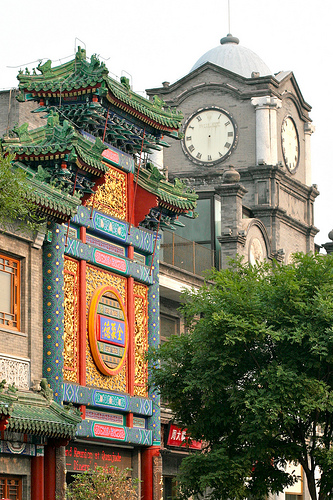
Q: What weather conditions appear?
A: It is cloudy.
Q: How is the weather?
A: It is cloudy.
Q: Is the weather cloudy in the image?
A: Yes, it is cloudy.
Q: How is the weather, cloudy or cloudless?
A: It is cloudy.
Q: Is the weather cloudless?
A: No, it is cloudy.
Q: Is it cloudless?
A: No, it is cloudy.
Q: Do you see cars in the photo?
A: No, there are no cars.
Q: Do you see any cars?
A: No, there are no cars.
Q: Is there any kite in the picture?
A: No, there are no kites.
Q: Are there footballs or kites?
A: No, there are no kites or footballs.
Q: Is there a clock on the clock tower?
A: Yes, there are clocks on the clock tower.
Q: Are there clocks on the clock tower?
A: Yes, there are clocks on the clock tower.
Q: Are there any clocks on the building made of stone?
A: Yes, there are clocks on the clock tower.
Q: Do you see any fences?
A: Yes, there is a fence.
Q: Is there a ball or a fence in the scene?
A: Yes, there is a fence.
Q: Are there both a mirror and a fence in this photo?
A: No, there is a fence but no mirrors.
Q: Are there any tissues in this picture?
A: No, there are no tissues.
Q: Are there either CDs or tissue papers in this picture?
A: No, there are no tissue papers or cds.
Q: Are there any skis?
A: No, there are no skis.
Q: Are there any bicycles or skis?
A: No, there are no skis or bicycles.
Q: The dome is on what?
A: The dome is on the clock tower.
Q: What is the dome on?
A: The dome is on the clock tower.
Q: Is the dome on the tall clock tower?
A: Yes, the dome is on the clock tower.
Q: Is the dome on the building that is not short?
A: Yes, the dome is on the clock tower.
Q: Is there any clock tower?
A: Yes, there is a clock tower.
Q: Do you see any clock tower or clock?
A: Yes, there is a clock tower.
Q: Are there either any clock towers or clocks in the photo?
A: Yes, there is a clock tower.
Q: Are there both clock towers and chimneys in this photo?
A: No, there is a clock tower but no chimneys.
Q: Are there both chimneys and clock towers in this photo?
A: No, there is a clock tower but no chimneys.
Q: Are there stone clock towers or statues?
A: Yes, there is a stone clock tower.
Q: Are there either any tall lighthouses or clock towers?
A: Yes, there is a tall clock tower.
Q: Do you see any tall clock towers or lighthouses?
A: Yes, there is a tall clock tower.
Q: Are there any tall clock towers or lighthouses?
A: Yes, there is a tall clock tower.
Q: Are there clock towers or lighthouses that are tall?
A: Yes, the clock tower is tall.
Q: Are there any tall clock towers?
A: Yes, there is a tall clock tower.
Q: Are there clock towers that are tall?
A: Yes, there is a clock tower that is tall.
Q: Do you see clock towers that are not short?
A: Yes, there is a tall clock tower.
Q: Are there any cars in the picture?
A: No, there are no cars.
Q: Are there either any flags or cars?
A: No, there are no cars or flags.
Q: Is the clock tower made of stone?
A: Yes, the clock tower is made of stone.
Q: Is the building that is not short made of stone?
A: Yes, the clock tower is made of stone.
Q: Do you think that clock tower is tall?
A: Yes, the clock tower is tall.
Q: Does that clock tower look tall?
A: Yes, the clock tower is tall.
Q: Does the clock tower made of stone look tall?
A: Yes, the clock tower is tall.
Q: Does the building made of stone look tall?
A: Yes, the clock tower is tall.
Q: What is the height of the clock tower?
A: The clock tower is tall.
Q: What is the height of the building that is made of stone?
A: The clock tower is tall.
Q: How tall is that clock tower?
A: The clock tower is tall.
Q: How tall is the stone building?
A: The clock tower is tall.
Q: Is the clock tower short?
A: No, the clock tower is tall.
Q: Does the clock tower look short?
A: No, the clock tower is tall.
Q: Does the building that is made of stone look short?
A: No, the clock tower is tall.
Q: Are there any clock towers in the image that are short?
A: No, there is a clock tower but it is tall.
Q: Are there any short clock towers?
A: No, there is a clock tower but it is tall.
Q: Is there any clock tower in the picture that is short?
A: No, there is a clock tower but it is tall.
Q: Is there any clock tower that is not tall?
A: No, there is a clock tower but it is tall.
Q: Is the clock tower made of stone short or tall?
A: The clock tower is tall.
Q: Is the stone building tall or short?
A: The clock tower is tall.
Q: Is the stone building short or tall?
A: The clock tower is tall.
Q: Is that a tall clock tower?
A: Yes, that is a tall clock tower.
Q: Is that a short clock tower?
A: No, that is a tall clock tower.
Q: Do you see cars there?
A: No, there are no cars.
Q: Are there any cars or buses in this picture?
A: No, there are no cars or buses.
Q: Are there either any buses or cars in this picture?
A: No, there are no cars or buses.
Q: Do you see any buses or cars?
A: No, there are no cars or buses.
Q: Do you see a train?
A: No, there are no trains.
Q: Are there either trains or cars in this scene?
A: No, there are no trains or cars.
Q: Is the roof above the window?
A: Yes, the roof is above the window.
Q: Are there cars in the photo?
A: No, there are no cars.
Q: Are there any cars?
A: No, there are no cars.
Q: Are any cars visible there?
A: No, there are no cars.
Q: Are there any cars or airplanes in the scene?
A: No, there are no cars or airplanes.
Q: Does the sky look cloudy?
A: Yes, the sky is cloudy.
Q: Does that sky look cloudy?
A: Yes, the sky is cloudy.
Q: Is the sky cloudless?
A: No, the sky is cloudy.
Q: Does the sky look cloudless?
A: No, the sky is cloudy.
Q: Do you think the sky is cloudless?
A: No, the sky is cloudy.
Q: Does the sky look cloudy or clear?
A: The sky is cloudy.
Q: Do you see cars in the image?
A: No, there are no cars.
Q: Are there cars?
A: No, there are no cars.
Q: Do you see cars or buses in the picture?
A: No, there are no cars or buses.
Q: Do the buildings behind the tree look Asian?
A: Yes, the buildings are asian.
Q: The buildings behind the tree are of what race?
A: The buildings are asian.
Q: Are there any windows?
A: Yes, there is a window.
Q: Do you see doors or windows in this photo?
A: Yes, there is a window.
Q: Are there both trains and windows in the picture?
A: No, there is a window but no trains.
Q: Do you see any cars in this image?
A: No, there are no cars.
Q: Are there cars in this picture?
A: No, there are no cars.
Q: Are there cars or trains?
A: No, there are no cars or trains.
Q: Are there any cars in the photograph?
A: No, there are no cars.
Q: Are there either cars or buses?
A: No, there are no cars or buses.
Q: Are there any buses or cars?
A: No, there are no cars or buses.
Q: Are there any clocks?
A: Yes, there is a clock.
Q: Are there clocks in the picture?
A: Yes, there is a clock.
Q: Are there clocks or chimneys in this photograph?
A: Yes, there is a clock.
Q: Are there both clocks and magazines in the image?
A: No, there is a clock but no magazines.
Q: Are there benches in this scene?
A: No, there are no benches.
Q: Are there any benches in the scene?
A: No, there are no benches.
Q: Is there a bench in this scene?
A: No, there are no benches.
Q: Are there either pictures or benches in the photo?
A: No, there are no benches or pictures.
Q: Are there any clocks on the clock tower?
A: Yes, there is a clock on the clock tower.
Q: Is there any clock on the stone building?
A: Yes, there is a clock on the clock tower.